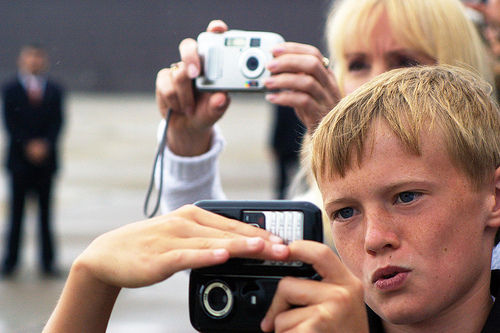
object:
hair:
[320, 3, 488, 92]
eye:
[349, 60, 368, 72]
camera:
[192, 29, 285, 94]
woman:
[153, 0, 500, 267]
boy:
[42, 63, 500, 332]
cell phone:
[189, 198, 325, 331]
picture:
[0, 1, 500, 333]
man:
[4, 41, 74, 279]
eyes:
[392, 188, 438, 208]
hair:
[306, 63, 499, 191]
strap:
[141, 105, 182, 219]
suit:
[5, 72, 67, 269]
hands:
[42, 203, 289, 333]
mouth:
[370, 264, 407, 289]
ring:
[170, 61, 183, 73]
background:
[3, 0, 499, 332]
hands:
[25, 138, 47, 162]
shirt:
[159, 127, 332, 219]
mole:
[388, 253, 396, 260]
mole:
[445, 247, 450, 255]